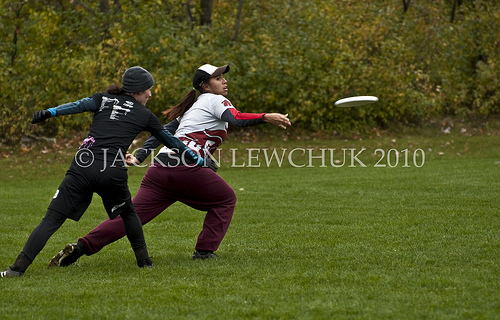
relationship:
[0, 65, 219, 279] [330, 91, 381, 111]
woman near frisbee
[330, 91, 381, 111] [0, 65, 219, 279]
frisbee near woman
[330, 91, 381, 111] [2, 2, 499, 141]
frisbee beside trees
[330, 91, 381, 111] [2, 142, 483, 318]
frisbee above grass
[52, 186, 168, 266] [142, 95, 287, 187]
leg outstretched behind body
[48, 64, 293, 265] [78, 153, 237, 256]
woman in sweat pants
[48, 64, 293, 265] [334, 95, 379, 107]
woman reaching for frisbee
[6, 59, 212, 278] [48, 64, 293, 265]
woman behind woman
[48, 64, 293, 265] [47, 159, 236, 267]
woman in sweatpants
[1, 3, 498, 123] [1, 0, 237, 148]
leaves on tree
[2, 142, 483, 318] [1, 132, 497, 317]
grass on ground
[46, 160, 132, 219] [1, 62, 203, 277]
shorts on person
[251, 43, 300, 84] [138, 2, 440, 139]
leaves on tree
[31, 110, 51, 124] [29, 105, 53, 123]
glove on hand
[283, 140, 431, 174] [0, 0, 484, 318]
writing across photo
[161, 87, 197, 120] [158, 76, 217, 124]
pony tail in hair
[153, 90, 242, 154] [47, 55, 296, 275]
shirt on girl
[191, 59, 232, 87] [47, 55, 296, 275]
hat on girl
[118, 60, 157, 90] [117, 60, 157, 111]
cap on head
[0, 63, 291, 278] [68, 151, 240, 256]
woman wearing sweat pants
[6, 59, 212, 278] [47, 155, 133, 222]
woman wearing shorts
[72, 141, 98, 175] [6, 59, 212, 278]
copyright symbol on woman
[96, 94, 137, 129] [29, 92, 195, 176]
letters on shirt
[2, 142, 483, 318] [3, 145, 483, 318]
grass in field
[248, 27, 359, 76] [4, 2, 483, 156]
leaves on trees